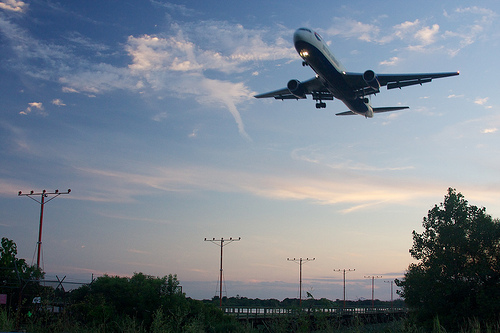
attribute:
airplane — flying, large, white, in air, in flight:
[254, 28, 460, 117]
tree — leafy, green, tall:
[394, 188, 499, 319]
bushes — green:
[63, 273, 237, 330]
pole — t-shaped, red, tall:
[15, 187, 71, 272]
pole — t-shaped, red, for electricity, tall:
[205, 234, 241, 296]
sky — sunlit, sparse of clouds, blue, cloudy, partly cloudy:
[0, 1, 499, 301]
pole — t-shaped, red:
[284, 255, 315, 300]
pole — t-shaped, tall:
[331, 266, 355, 301]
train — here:
[2, 294, 28, 307]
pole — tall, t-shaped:
[361, 271, 383, 300]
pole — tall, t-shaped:
[381, 277, 399, 301]